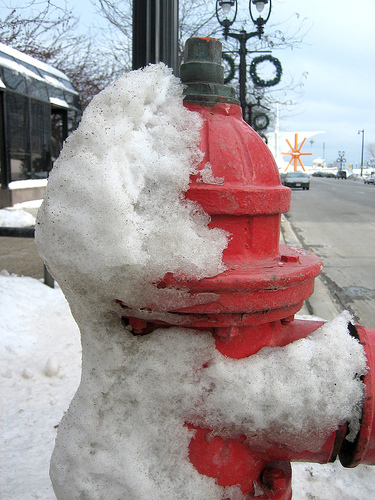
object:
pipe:
[284, 314, 375, 472]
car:
[286, 169, 312, 193]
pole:
[130, 2, 182, 74]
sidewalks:
[9, 170, 63, 229]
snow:
[60, 408, 88, 463]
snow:
[86, 340, 193, 459]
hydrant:
[38, 38, 375, 493]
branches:
[77, 45, 97, 93]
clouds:
[326, 88, 356, 115]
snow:
[155, 199, 220, 275]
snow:
[15, 347, 51, 388]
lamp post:
[355, 128, 373, 181]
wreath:
[246, 51, 282, 89]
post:
[228, 26, 260, 107]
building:
[0, 44, 84, 188]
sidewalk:
[0, 232, 55, 292]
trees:
[19, 8, 116, 91]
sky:
[281, 12, 314, 98]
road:
[312, 196, 369, 281]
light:
[214, 0, 273, 40]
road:
[338, 268, 373, 305]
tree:
[180, 0, 204, 39]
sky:
[319, 2, 374, 40]